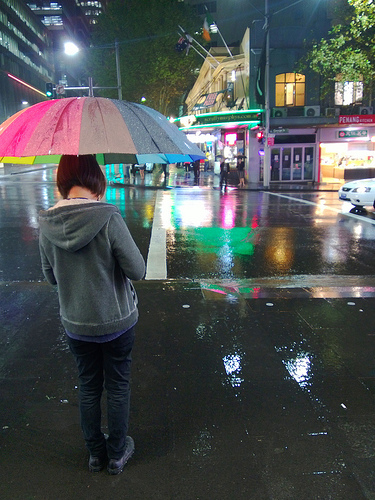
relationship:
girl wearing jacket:
[21, 154, 148, 487] [25, 208, 160, 330]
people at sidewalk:
[214, 149, 250, 193] [205, 140, 267, 204]